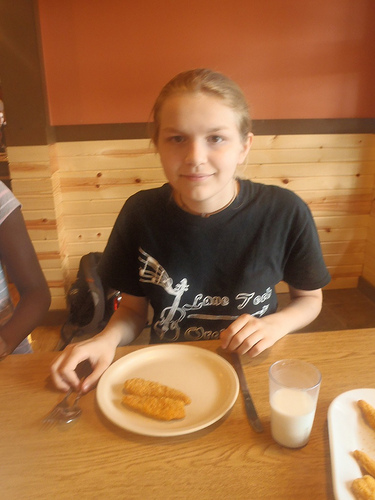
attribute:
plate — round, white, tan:
[92, 340, 244, 444]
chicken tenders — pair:
[117, 375, 195, 425]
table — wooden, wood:
[1, 327, 373, 499]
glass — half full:
[264, 354, 325, 453]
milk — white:
[265, 382, 320, 453]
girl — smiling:
[45, 65, 331, 395]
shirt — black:
[92, 176, 333, 347]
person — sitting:
[1, 172, 57, 365]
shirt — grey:
[1, 176, 32, 354]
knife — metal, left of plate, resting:
[223, 344, 267, 439]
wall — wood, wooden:
[1, 131, 375, 309]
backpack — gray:
[56, 253, 116, 344]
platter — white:
[324, 385, 374, 498]